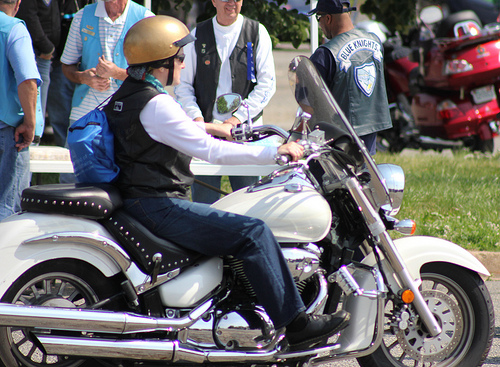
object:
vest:
[192, 15, 259, 123]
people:
[20, 0, 62, 118]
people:
[1, 0, 46, 222]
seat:
[20, 183, 196, 276]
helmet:
[123, 15, 197, 66]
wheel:
[0, 258, 121, 367]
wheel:
[460, 122, 494, 154]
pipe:
[0, 299, 214, 334]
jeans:
[124, 196, 309, 330]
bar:
[233, 124, 291, 144]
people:
[173, 0, 275, 205]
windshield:
[287, 55, 395, 210]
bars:
[276, 137, 309, 166]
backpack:
[67, 88, 154, 183]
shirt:
[174, 13, 277, 121]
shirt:
[139, 94, 279, 166]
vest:
[0, 11, 46, 138]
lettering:
[71, 154, 93, 177]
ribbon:
[247, 42, 257, 83]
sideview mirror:
[216, 93, 242, 114]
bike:
[0, 55, 495, 367]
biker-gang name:
[341, 40, 379, 60]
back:
[333, 29, 386, 112]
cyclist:
[107, 14, 350, 349]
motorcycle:
[380, 10, 500, 154]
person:
[60, 0, 158, 149]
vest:
[72, 0, 149, 107]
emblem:
[113, 101, 123, 111]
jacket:
[101, 75, 196, 200]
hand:
[15, 124, 35, 152]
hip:
[0, 122, 31, 159]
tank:
[210, 183, 332, 243]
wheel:
[356, 260, 493, 367]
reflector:
[401, 289, 414, 302]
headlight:
[376, 164, 405, 217]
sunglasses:
[174, 54, 186, 63]